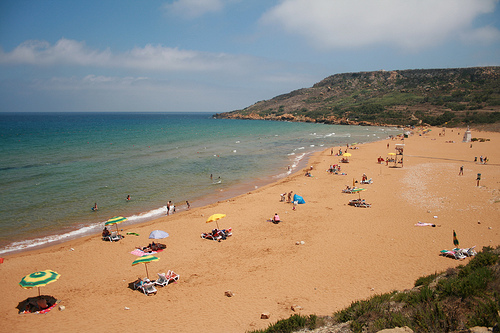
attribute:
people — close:
[266, 130, 484, 245]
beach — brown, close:
[5, 129, 479, 331]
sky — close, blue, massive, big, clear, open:
[1, 2, 493, 115]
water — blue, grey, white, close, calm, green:
[1, 114, 366, 252]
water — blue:
[5, 109, 408, 259]